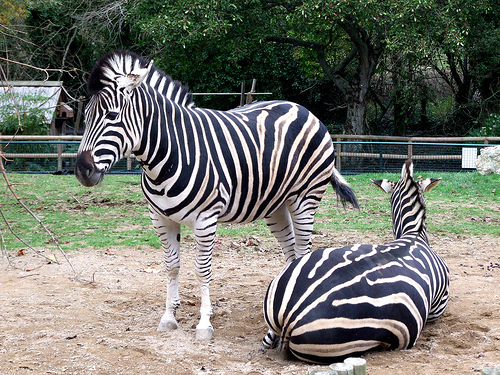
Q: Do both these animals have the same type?
A: Yes, all the animals are zebras.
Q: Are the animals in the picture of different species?
A: No, all the animals are zebras.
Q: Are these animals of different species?
A: No, all the animals are zebras.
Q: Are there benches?
A: No, there are no benches.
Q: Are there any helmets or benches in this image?
A: No, there are no benches or helmets.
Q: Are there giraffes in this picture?
A: No, there are no giraffes.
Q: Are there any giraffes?
A: No, there are no giraffes.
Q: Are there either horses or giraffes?
A: No, there are no giraffes or horses.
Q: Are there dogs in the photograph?
A: No, there are no dogs.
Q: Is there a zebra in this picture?
A: Yes, there is a zebra.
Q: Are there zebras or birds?
A: Yes, there is a zebra.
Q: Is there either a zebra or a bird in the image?
A: Yes, there is a zebra.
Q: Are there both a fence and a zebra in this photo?
A: Yes, there are both a zebra and a fence.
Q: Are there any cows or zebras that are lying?
A: Yes, the zebra is lying.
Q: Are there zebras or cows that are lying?
A: Yes, the zebra is lying.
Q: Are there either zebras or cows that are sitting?
A: Yes, the zebra is sitting.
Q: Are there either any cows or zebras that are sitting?
A: Yes, the zebra is sitting.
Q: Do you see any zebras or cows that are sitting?
A: Yes, the zebra is sitting.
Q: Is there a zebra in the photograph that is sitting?
A: Yes, there is a zebra that is sitting.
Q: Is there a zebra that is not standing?
A: Yes, there is a zebra that is sitting.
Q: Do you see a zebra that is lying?
A: Yes, there is a zebra that is lying.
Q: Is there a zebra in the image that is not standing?
A: Yes, there is a zebra that is lying.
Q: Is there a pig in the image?
A: No, there are no pigs.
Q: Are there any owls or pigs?
A: No, there are no pigs or owls.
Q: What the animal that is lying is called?
A: The animal is a zebra.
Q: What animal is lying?
A: The animal is a zebra.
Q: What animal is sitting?
A: The animal is a zebra.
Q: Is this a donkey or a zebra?
A: This is a zebra.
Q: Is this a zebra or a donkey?
A: This is a zebra.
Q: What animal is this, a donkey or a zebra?
A: This is a zebra.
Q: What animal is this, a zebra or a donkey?
A: This is a zebra.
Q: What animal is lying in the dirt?
A: The zebra is lying in the dirt.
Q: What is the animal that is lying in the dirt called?
A: The animal is a zebra.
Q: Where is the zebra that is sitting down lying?
A: The zebra is lying in the dirt.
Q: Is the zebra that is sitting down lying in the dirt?
A: Yes, the zebra is lying in the dirt.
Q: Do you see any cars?
A: No, there are no cars.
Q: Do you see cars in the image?
A: No, there are no cars.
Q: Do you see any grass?
A: Yes, there is grass.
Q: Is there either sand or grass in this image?
A: Yes, there is grass.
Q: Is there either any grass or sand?
A: Yes, there is grass.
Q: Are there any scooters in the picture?
A: No, there are no scooters.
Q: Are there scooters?
A: No, there are no scooters.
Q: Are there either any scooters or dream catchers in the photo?
A: No, there are no scooters or dream catchers.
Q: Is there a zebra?
A: Yes, there is a zebra.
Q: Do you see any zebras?
A: Yes, there is a zebra.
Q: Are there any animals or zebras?
A: Yes, there is a zebra.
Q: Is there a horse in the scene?
A: No, there are no horses.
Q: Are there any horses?
A: No, there are no horses.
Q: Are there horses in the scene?
A: No, there are no horses.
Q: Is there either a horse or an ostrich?
A: No, there are no horses or ostriches.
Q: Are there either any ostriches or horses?
A: No, there are no horses or ostriches.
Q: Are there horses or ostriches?
A: No, there are no horses or ostriches.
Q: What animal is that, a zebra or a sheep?
A: That is a zebra.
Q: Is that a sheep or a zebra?
A: That is a zebra.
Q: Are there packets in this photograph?
A: No, there are no packets.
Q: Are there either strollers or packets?
A: No, there are no packets or strollers.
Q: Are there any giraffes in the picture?
A: No, there are no giraffes.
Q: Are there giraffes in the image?
A: No, there are no giraffes.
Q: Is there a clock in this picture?
A: No, there are no clocks.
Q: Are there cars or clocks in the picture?
A: No, there are no clocks or cars.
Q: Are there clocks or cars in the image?
A: No, there are no clocks or cars.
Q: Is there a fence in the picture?
A: Yes, there is a fence.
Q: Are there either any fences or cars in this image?
A: Yes, there is a fence.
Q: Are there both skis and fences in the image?
A: No, there is a fence but no skis.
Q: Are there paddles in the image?
A: No, there are no paddles.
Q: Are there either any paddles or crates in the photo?
A: No, there are no paddles or crates.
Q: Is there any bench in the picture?
A: No, there are no benches.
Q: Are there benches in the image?
A: No, there are no benches.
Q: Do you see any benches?
A: No, there are no benches.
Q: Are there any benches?
A: No, there are no benches.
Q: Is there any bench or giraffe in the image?
A: No, there are no benches or giraffes.